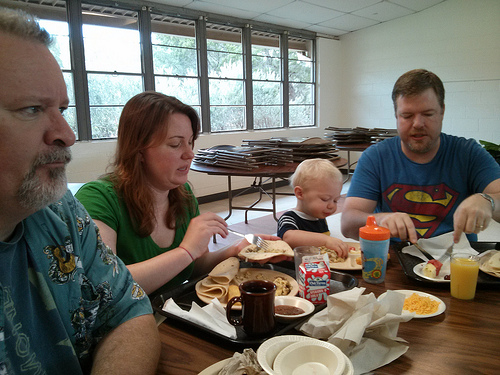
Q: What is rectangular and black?
A: The tray.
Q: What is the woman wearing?
A: A green shirt.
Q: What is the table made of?
A: Wood.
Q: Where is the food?
A: On the table.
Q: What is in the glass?
A: Orange juice.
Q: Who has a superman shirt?
A: The father.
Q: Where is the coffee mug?
A: On the table.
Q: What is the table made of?
A: Wood.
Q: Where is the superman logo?
A: On the blue shirt.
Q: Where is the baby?
A: In between the mother and father.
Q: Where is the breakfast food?
A: On the table.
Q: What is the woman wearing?
A: Green shirt.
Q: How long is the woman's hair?
A: Long.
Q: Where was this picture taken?
A: Restaurant.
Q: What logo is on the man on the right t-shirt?
A: Superman.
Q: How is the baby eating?
A: With his hands.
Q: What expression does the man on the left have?
A: Angry.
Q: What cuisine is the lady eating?
A: Mexican.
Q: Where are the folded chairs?
A: On the table.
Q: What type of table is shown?
A: Wood.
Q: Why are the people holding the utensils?
A: They are eating.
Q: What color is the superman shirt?
A: Blue.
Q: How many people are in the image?
A: Four.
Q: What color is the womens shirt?
A: Green.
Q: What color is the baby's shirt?
A: Black.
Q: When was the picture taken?
A: During the day.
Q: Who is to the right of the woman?
A: A man.